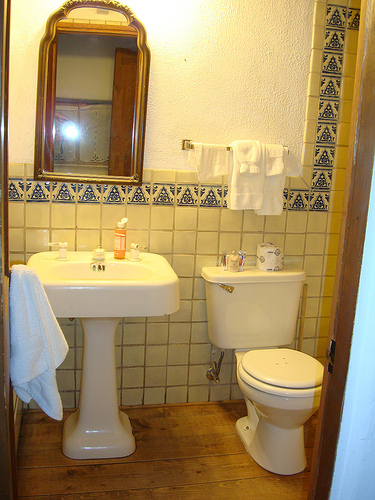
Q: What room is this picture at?
A: It is at the bathroom.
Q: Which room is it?
A: It is a bathroom.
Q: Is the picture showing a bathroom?
A: Yes, it is showing a bathroom.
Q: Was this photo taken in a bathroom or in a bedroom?
A: It was taken at a bathroom.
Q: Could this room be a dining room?
A: No, it is a bathroom.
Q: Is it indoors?
A: Yes, it is indoors.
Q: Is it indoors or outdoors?
A: It is indoors.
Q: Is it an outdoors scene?
A: No, it is indoors.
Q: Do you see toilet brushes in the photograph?
A: No, there are no toilet brushes.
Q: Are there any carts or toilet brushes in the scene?
A: No, there are no toilet brushes or carts.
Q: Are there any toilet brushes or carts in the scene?
A: No, there are no toilet brushes or carts.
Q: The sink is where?
A: The sink is in the bathroom.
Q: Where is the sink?
A: The sink is in the bathroom.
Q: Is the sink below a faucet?
A: No, the sink is below a mirror.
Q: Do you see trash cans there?
A: No, there are no trash cans.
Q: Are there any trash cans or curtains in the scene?
A: No, there are no trash cans or curtains.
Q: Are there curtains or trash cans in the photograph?
A: No, there are no trash cans or curtains.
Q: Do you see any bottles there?
A: Yes, there is a bottle.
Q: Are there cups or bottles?
A: Yes, there is a bottle.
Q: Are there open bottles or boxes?
A: Yes, there is an open bottle.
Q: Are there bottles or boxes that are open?
A: Yes, the bottle is open.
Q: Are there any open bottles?
A: Yes, there is an open bottle.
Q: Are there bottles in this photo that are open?
A: Yes, there is a bottle that is open.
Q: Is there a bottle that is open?
A: Yes, there is a bottle that is open.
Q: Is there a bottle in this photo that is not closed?
A: Yes, there is a open bottle.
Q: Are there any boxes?
A: No, there are no boxes.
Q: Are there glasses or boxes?
A: No, there are no boxes or glasses.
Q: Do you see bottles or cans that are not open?
A: No, there is a bottle but it is open.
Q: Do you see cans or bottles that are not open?
A: No, there is a bottle but it is open.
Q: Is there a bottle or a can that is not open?
A: No, there is a bottle but it is open.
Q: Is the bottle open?
A: Yes, the bottle is open.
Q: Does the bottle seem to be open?
A: Yes, the bottle is open.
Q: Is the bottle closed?
A: No, the bottle is open.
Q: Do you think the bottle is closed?
A: No, the bottle is open.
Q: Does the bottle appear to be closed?
A: No, the bottle is open.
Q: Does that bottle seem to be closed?
A: No, the bottle is open.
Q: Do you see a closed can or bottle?
A: No, there is a bottle but it is open.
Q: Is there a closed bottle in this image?
A: No, there is a bottle but it is open.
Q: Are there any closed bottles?
A: No, there is a bottle but it is open.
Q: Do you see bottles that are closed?
A: No, there is a bottle but it is open.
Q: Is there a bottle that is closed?
A: No, there is a bottle but it is open.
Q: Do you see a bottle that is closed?
A: No, there is a bottle but it is open.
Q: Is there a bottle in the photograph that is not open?
A: No, there is a bottle but it is open.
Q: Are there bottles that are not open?
A: No, there is a bottle but it is open.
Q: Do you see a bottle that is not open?
A: No, there is a bottle but it is open.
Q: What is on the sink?
A: The bottle is on the sink.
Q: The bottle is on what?
A: The bottle is on the sink.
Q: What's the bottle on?
A: The bottle is on the sink.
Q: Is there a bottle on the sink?
A: Yes, there is a bottle on the sink.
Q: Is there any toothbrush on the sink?
A: No, there is a bottle on the sink.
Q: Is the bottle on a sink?
A: Yes, the bottle is on a sink.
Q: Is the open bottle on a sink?
A: Yes, the bottle is on a sink.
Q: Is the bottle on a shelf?
A: No, the bottle is on a sink.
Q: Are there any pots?
A: No, there are no pots.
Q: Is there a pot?
A: No, there are no pots.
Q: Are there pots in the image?
A: No, there are no pots.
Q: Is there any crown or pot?
A: No, there are no pots or crowns.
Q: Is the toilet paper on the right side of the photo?
A: Yes, the toilet paper is on the right of the image.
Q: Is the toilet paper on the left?
A: No, the toilet paper is on the right of the image.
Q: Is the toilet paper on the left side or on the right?
A: The toilet paper is on the right of the image.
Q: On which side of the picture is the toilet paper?
A: The toilet paper is on the right of the image.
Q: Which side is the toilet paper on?
A: The toilet paper is on the right of the image.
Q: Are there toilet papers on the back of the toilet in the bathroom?
A: Yes, there is a toilet paper on the back of the toilet.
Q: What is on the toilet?
A: The toilet paper is on the toilet.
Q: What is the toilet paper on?
A: The toilet paper is on the toilet.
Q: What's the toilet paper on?
A: The toilet paper is on the toilet.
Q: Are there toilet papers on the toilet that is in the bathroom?
A: Yes, there is a toilet paper on the toilet.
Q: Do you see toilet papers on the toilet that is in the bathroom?
A: Yes, there is a toilet paper on the toilet.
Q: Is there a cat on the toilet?
A: No, there is a toilet paper on the toilet.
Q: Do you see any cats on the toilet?
A: No, there is a toilet paper on the toilet.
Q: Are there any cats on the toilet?
A: No, there is a toilet paper on the toilet.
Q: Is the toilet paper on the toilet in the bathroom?
A: Yes, the toilet paper is on the toilet.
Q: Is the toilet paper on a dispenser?
A: No, the toilet paper is on the toilet.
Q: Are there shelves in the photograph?
A: No, there are no shelves.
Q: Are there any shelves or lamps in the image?
A: No, there are no shelves or lamps.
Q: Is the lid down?
A: Yes, the lid is down.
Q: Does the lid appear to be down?
A: Yes, the lid is down.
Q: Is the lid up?
A: No, the lid is down.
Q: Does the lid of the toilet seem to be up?
A: No, the lid is down.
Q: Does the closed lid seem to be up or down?
A: The lid is down.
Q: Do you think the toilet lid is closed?
A: Yes, the lid is closed.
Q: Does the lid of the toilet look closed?
A: Yes, the lid is closed.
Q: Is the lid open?
A: No, the lid is closed.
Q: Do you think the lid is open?
A: No, the lid is closed.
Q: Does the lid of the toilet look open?
A: No, the lid is closed.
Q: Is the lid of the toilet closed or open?
A: The lid is closed.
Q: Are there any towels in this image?
A: Yes, there is a towel.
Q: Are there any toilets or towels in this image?
A: Yes, there is a towel.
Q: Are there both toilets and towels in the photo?
A: Yes, there are both a towel and a toilet.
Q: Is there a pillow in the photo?
A: No, there are no pillows.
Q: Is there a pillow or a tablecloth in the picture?
A: No, there are no pillows or tablecloths.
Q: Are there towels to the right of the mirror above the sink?
A: Yes, there is a towel to the right of the mirror.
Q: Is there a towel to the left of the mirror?
A: No, the towel is to the right of the mirror.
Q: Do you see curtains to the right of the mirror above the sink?
A: No, there is a towel to the right of the mirror.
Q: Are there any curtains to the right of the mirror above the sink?
A: No, there is a towel to the right of the mirror.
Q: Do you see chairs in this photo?
A: No, there are no chairs.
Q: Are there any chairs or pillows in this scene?
A: No, there are no chairs or pillows.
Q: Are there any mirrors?
A: Yes, there is a mirror.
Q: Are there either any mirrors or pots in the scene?
A: Yes, there is a mirror.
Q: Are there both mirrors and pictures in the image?
A: No, there is a mirror but no pictures.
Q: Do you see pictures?
A: No, there are no pictures.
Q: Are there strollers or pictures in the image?
A: No, there are no pictures or strollers.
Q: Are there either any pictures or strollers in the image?
A: No, there are no pictures or strollers.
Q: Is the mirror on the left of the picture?
A: Yes, the mirror is on the left of the image.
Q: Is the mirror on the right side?
A: No, the mirror is on the left of the image.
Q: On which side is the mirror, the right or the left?
A: The mirror is on the left of the image.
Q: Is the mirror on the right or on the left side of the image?
A: The mirror is on the left of the image.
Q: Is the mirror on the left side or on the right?
A: The mirror is on the left of the image.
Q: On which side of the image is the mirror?
A: The mirror is on the left of the image.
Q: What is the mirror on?
A: The mirror is on the wall.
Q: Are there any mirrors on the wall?
A: Yes, there is a mirror on the wall.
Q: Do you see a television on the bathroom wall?
A: No, there is a mirror on the wall.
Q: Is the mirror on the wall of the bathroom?
A: Yes, the mirror is on the wall.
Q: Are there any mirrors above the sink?
A: Yes, there is a mirror above the sink.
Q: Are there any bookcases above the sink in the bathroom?
A: No, there is a mirror above the sink.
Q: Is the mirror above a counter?
A: No, the mirror is above the sink.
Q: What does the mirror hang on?
A: The mirror hangs on the wall.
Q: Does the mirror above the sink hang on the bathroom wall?
A: Yes, the mirror hangs on the wall.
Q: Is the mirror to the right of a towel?
A: No, the mirror is to the left of a towel.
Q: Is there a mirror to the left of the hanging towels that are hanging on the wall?
A: Yes, there is a mirror to the left of the towels.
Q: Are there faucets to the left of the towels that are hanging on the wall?
A: No, there is a mirror to the left of the towels.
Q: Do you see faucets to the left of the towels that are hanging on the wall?
A: No, there is a mirror to the left of the towels.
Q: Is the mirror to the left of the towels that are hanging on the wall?
A: Yes, the mirror is to the left of the towels.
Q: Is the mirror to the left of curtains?
A: No, the mirror is to the left of the towels.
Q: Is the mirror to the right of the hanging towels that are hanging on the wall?
A: No, the mirror is to the left of the towels.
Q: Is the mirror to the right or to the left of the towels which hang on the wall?
A: The mirror is to the left of the towels.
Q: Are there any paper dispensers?
A: No, there are no paper dispensers.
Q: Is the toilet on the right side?
A: Yes, the toilet is on the right of the image.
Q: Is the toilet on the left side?
A: No, the toilet is on the right of the image.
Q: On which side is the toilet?
A: The toilet is on the right of the image.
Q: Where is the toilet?
A: The toilet is in the bathroom.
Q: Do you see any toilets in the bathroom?
A: Yes, there is a toilet in the bathroom.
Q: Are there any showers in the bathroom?
A: No, there is a toilet in the bathroom.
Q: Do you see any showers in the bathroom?
A: No, there is a toilet in the bathroom.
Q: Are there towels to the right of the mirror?
A: Yes, there are towels to the right of the mirror.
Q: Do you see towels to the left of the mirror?
A: No, the towels are to the right of the mirror.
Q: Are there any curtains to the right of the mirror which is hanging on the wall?
A: No, there are towels to the right of the mirror.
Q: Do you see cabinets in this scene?
A: No, there are no cabinets.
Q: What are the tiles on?
A: The tiles are on the wall.